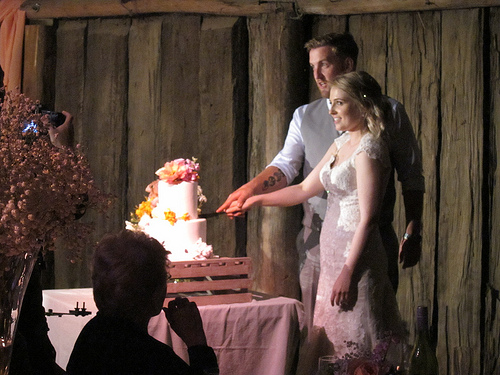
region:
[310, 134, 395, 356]
A white dress in the photo.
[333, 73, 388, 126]
A blonde hair in the photo.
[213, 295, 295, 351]
A white table cloth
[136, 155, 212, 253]
A cake in the photo.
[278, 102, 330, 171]
A white shirt in the photo.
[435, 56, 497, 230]
A wooden wall in the photo.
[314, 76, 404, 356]
A woman in the photo.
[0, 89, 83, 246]
A flower in the photo.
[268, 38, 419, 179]
A man in the photo.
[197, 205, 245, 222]
A knife in the photo.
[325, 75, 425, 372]
This is a woman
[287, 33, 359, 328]
This is a man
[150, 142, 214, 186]
This is a cake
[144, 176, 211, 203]
This is a cake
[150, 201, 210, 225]
This is a cake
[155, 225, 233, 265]
This is a cake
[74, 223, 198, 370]
This is a person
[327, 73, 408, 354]
This is a person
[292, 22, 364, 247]
This is a person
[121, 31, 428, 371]
bride and groom cutting wedding cake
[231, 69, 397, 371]
bride is wearing white sleeveless dress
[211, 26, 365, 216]
groom has tattoo on forearm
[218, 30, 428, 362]
groom beside bride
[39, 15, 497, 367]
rough wood wall behind man and woman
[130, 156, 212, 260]
cake with two tiers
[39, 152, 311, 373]
cake on table with rose tablecloth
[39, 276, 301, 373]
table is square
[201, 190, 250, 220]
man's hand and woman's hand holding knife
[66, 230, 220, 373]
shadowed person raising hand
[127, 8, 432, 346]
bride and groom cutting wedding cake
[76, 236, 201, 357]
person watching cake cutting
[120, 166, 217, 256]
white two tier wedding cake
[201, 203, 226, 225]
knife cutting wedding cake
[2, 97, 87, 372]
vase with flowers in it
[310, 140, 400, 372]
wedding gown of bride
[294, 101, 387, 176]
gray vest of groom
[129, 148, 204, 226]
flower decorations on wedding cake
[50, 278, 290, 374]
white tablecloth on table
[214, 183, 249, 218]
groom's hand on top of bride's hand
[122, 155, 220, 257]
The cake has two tiers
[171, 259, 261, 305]
The wood crate is brown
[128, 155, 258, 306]
Cake on a crate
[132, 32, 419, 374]
Man and woman cutting a cake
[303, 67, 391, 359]
The woman is wearing a white dress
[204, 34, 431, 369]
The man and woman are standing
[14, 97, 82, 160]
The camera is black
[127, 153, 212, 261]
Yellow and pink flowers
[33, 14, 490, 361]
The fence is wood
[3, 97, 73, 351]
Pink flowers in a clear vase